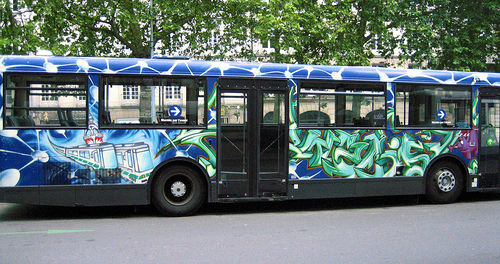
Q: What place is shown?
A: It is a road.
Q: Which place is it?
A: It is a road.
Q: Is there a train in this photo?
A: Yes, there is a train.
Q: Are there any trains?
A: Yes, there is a train.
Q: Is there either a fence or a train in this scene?
A: Yes, there is a train.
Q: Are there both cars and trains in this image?
A: No, there is a train but no cars.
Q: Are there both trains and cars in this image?
A: No, there is a train but no cars.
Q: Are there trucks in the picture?
A: No, there are no trucks.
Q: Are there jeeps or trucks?
A: No, there are no trucks or jeeps.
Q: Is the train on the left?
A: Yes, the train is on the left of the image.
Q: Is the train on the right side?
A: No, the train is on the left of the image.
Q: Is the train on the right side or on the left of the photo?
A: The train is on the left of the image.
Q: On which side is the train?
A: The train is on the left of the image.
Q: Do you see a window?
A: Yes, there is a window.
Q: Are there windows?
A: Yes, there is a window.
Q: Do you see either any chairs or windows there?
A: Yes, there is a window.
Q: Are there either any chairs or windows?
A: Yes, there is a window.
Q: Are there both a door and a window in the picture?
A: Yes, there are both a window and a door.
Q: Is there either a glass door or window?
A: Yes, there is a glass window.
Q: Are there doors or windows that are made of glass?
A: Yes, the window is made of glass.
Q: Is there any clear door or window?
A: Yes, there is a clear window.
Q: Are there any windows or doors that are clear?
A: Yes, the window is clear.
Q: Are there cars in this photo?
A: No, there are no cars.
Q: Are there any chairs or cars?
A: No, there are no cars or chairs.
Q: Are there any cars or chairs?
A: No, there are no cars or chairs.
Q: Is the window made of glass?
A: Yes, the window is made of glass.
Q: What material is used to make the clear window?
A: The window is made of glass.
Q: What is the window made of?
A: The window is made of glass.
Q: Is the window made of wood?
A: No, the window is made of glass.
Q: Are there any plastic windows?
A: No, there is a window but it is made of glass.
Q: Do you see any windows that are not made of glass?
A: No, there is a window but it is made of glass.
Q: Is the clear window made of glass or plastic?
A: The window is made of glass.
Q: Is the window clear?
A: Yes, the window is clear.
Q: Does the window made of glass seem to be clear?
A: Yes, the window is clear.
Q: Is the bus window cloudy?
A: No, the window is clear.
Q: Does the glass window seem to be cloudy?
A: No, the window is clear.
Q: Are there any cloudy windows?
A: No, there is a window but it is clear.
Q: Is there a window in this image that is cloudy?
A: No, there is a window but it is clear.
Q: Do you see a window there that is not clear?
A: No, there is a window but it is clear.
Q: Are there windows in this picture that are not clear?
A: No, there is a window but it is clear.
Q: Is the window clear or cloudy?
A: The window is clear.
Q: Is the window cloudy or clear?
A: The window is clear.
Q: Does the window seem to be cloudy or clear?
A: The window is clear.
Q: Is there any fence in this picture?
A: No, there are no fences.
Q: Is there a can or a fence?
A: No, there are no fences or cans.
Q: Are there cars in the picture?
A: No, there are no cars.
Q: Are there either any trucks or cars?
A: No, there are no cars or trucks.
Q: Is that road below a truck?
A: No, the road is below the bus.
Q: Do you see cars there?
A: No, there are no cars.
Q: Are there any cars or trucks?
A: No, there are no cars or trucks.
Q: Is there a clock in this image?
A: No, there are no clocks.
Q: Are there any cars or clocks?
A: No, there are no clocks or cars.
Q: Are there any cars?
A: No, there are no cars.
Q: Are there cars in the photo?
A: No, there are no cars.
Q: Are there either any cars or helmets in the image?
A: No, there are no cars or helmets.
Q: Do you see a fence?
A: No, there are no fences.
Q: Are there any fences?
A: No, there are no fences.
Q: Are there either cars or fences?
A: No, there are no fences or cars.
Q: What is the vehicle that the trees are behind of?
A: The vehicle is a bus.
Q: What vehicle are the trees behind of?
A: The trees are behind the bus.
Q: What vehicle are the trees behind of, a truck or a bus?
A: The trees are behind a bus.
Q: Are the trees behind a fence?
A: No, the trees are behind the bus.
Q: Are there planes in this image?
A: No, there are no planes.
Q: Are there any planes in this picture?
A: No, there are no planes.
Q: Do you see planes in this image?
A: No, there are no planes.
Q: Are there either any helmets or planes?
A: No, there are no planes or helmets.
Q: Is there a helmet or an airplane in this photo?
A: No, there are no airplanes or helmets.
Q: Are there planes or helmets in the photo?
A: No, there are no planes or helmets.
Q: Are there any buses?
A: Yes, there is a bus.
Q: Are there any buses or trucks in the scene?
A: Yes, there is a bus.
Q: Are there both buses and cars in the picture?
A: No, there is a bus but no cars.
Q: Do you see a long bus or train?
A: Yes, there is a long bus.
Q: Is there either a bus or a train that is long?
A: Yes, the bus is long.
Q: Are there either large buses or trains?
A: Yes, there is a large bus.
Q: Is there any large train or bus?
A: Yes, there is a large bus.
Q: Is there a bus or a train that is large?
A: Yes, the bus is large.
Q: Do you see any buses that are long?
A: Yes, there is a long bus.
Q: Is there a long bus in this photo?
A: Yes, there is a long bus.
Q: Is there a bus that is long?
A: Yes, there is a bus that is long.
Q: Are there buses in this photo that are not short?
A: Yes, there is a long bus.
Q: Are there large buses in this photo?
A: Yes, there is a large bus.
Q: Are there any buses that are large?
A: Yes, there is a bus that is large.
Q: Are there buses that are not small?
A: Yes, there is a large bus.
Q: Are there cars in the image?
A: No, there are no cars.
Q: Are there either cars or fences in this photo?
A: No, there are no cars or fences.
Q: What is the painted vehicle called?
A: The vehicle is a bus.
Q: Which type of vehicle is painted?
A: The vehicle is a bus.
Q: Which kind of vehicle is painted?
A: The vehicle is a bus.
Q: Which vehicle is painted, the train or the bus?
A: The bus is painted.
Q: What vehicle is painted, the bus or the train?
A: The bus is painted.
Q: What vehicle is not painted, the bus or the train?
A: The train is not painted.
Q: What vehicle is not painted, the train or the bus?
A: The train is not painted.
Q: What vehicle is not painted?
A: The vehicle is a train.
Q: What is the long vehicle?
A: The vehicle is a bus.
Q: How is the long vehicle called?
A: The vehicle is a bus.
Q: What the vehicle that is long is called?
A: The vehicle is a bus.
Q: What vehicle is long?
A: The vehicle is a bus.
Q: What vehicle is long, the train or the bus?
A: The bus is long.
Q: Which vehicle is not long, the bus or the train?
A: The train is not long.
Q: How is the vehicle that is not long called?
A: The vehicle is a train.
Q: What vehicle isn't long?
A: The vehicle is a train.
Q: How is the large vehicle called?
A: The vehicle is a bus.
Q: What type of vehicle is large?
A: The vehicle is a bus.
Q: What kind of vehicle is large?
A: The vehicle is a bus.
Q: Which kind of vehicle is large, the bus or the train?
A: The bus is large.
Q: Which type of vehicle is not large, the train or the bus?
A: The train is not large.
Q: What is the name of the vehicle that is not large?
A: The vehicle is a train.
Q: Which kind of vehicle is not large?
A: The vehicle is a train.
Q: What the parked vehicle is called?
A: The vehicle is a bus.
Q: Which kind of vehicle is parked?
A: The vehicle is a bus.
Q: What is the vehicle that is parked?
A: The vehicle is a bus.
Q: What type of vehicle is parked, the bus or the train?
A: The bus is parked.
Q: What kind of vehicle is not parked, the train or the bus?
A: The train is not parked.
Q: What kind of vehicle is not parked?
A: The vehicle is a train.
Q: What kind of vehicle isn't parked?
A: The vehicle is a train.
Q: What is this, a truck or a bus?
A: This is a bus.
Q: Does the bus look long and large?
A: Yes, the bus is long and large.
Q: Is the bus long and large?
A: Yes, the bus is long and large.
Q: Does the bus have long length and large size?
A: Yes, the bus is long and large.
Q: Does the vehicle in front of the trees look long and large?
A: Yes, the bus is long and large.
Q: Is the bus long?
A: Yes, the bus is long.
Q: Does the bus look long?
A: Yes, the bus is long.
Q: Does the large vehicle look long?
A: Yes, the bus is long.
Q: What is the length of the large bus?
A: The bus is long.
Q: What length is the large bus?
A: The bus is long.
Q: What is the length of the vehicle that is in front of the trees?
A: The bus is long.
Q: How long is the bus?
A: The bus is long.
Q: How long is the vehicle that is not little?
A: The bus is long.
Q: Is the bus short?
A: No, the bus is long.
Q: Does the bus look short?
A: No, the bus is long.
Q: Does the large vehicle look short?
A: No, the bus is long.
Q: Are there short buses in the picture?
A: No, there is a bus but it is long.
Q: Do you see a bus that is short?
A: No, there is a bus but it is long.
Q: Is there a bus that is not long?
A: No, there is a bus but it is long.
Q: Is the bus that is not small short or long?
A: The bus is long.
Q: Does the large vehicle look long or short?
A: The bus is long.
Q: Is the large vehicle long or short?
A: The bus is long.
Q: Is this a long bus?
A: Yes, this is a long bus.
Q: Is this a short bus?
A: No, this is a long bus.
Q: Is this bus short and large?
A: No, the bus is large but long.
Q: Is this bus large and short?
A: No, the bus is large but long.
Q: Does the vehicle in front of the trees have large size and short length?
A: No, the bus is large but long.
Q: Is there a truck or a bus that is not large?
A: No, there is a bus but it is large.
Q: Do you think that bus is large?
A: Yes, the bus is large.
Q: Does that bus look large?
A: Yes, the bus is large.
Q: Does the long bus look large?
A: Yes, the bus is large.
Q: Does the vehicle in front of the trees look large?
A: Yes, the bus is large.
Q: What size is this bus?
A: The bus is large.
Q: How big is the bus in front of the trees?
A: The bus is large.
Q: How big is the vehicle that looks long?
A: The bus is large.